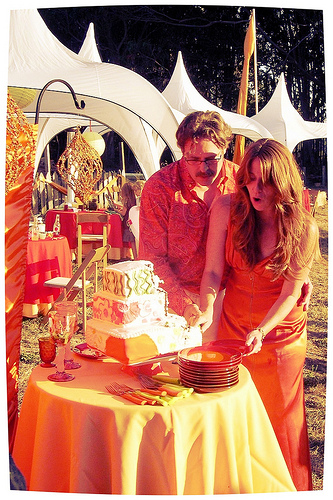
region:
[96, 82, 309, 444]
man and woman cutting a wedding cake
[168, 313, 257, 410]
orange plates on a table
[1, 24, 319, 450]
orange themed wedding decor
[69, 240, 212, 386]
uneven multicolored wedding cake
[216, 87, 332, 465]
woman with her mouth open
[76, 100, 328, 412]
man and woman cutting cake together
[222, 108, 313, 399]
woman with long hair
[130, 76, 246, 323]
man with glasses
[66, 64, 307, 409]
just married couple in orange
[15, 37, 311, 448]
wedding reception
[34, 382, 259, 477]
yellow mustard table cloth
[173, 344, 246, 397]
stack of orange glass plates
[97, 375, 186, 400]
group of orange and yellow forks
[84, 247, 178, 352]
colorful wedding cake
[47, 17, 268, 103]
white tents for wedding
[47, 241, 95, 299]
wooden folding chair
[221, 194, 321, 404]
range womans wedding dress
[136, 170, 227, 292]
paisley orange grooms shirt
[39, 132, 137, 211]
gold glitter handing chandalier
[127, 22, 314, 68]
dark green forest in back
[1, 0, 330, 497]
A photo of a celebration.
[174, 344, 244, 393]
A stack of red-orange dishes.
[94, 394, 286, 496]
A yellow table cloth.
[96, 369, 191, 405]
A bunch of orange forks.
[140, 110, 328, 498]
A woman and a man.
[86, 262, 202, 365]
A three layer cake.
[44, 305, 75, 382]
A tall gaudy goblet.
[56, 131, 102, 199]
A gold hanging decoration.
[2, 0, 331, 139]
The top of the white tents.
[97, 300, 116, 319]
The flower design on the cake.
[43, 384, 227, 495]
the tablecloth is white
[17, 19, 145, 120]
the tent is white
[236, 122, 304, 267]
her hair is long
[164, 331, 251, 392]
the dishes are stacked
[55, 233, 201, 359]
the cake is white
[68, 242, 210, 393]
the cake is three layers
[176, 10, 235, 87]
the trees are dark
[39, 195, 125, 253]
the cloth is red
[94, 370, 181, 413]
there are many forks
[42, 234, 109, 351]
the chair is wooden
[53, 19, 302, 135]
points on top of white tents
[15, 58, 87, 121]
curved black metal hook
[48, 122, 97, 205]
diamond-shaped structure made of orange and yellow beads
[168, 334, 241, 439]
stack of red plates on yellow tablecloth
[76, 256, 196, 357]
cake made with different icing and design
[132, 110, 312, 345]
man and woman with hands on cake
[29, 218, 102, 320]
chair by round table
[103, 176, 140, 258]
people busy at a table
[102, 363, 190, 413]
forks with orange and yellow handles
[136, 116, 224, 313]
man wearing paisley shirt in colors matching party theme